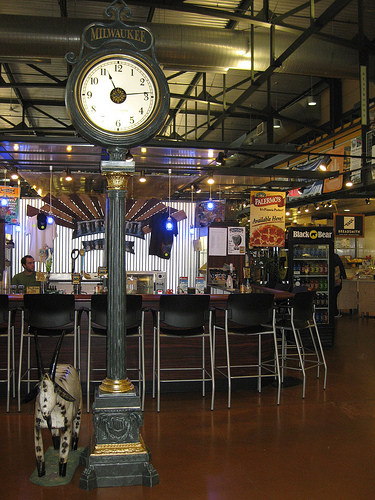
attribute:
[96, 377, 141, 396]
metal — golden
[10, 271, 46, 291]
shirt — green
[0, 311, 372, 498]
floors — shiny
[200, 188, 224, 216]
light — blue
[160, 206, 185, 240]
light — blue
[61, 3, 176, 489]
clock post — black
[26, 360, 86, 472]
goat — gray and black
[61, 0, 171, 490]
clock — gold, black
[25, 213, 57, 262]
shirt — white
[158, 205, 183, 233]
light — blue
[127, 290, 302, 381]
stools — black, silver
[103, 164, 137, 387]
lamp post — gold and green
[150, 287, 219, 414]
chair — bar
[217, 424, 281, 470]
tiled floor — brown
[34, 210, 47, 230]
cap — black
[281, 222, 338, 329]
cooler — black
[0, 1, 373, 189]
beams — silver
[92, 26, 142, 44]
lettering — brass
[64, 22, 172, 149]
clock — black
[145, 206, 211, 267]
shirt — black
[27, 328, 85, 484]
goat sculpture — white and black